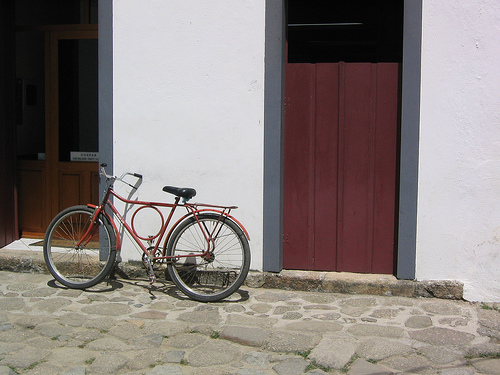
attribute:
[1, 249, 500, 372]
ground — stone, gray, grey, cement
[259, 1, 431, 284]
door — brown, closed, wood, red, wooden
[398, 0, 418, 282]
edges — gray, grey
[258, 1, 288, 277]
edges — gray, grey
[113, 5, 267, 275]
walls — gray, white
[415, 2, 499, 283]
walls — gray, white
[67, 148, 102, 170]
plate — large, white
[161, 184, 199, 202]
seat — black, shiny, large, leather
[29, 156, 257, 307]
bike — red, leaning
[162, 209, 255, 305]
tire — large, rubber, rear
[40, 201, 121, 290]
tire — large, rubber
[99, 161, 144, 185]
bars — silver, black